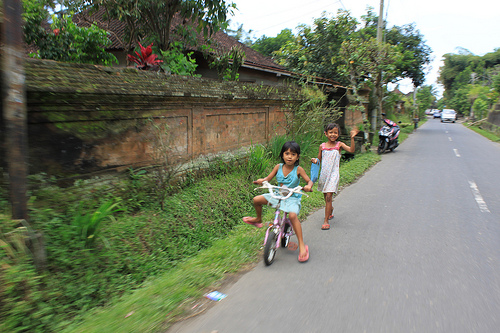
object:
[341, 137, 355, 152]
left arm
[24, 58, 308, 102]
roof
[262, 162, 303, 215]
outfit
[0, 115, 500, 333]
ground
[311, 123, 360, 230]
girl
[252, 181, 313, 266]
bike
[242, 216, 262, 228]
flip flops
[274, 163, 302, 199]
top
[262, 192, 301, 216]
skirt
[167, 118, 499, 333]
road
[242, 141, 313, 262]
girls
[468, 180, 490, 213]
line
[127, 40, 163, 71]
red flower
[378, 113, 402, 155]
motorcycle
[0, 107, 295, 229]
wall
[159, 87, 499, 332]
street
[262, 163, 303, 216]
blue dress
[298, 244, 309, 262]
flip flops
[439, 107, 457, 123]
car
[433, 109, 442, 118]
car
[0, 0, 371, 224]
building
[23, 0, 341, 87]
roof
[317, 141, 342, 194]
dress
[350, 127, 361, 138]
hand